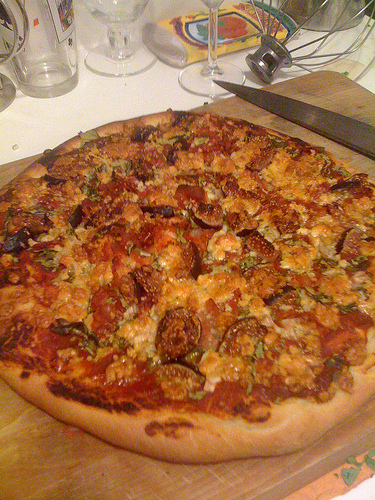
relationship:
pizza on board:
[2, 104, 375, 462] [0, 69, 374, 498]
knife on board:
[213, 75, 374, 159] [0, 69, 374, 498]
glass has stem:
[179, 1, 247, 96] [198, 9, 223, 75]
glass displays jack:
[5, 3, 81, 100] [46, 1, 77, 43]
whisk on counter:
[243, 1, 374, 83] [4, 0, 374, 499]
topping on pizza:
[153, 304, 204, 362] [2, 104, 375, 462]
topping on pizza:
[245, 147, 282, 170] [2, 104, 375, 462]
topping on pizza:
[240, 228, 285, 262] [2, 104, 375, 462]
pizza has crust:
[2, 104, 375, 462] [36, 401, 350, 459]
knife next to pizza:
[213, 75, 374, 159] [2, 104, 375, 462]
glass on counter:
[81, 1, 159, 78] [4, 0, 374, 499]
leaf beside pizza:
[336, 449, 374, 492] [2, 104, 375, 462]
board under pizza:
[0, 69, 374, 498] [2, 104, 375, 462]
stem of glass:
[198, 9, 223, 75] [179, 1, 247, 96]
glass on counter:
[5, 3, 81, 100] [4, 0, 374, 499]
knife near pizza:
[213, 75, 374, 159] [2, 104, 375, 462]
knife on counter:
[213, 75, 374, 159] [4, 0, 374, 499]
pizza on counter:
[2, 104, 375, 462] [4, 0, 374, 499]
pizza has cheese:
[2, 104, 375, 462] [165, 270, 241, 304]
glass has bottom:
[179, 1, 247, 96] [179, 58, 248, 98]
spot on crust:
[146, 418, 198, 441] [36, 401, 350, 459]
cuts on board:
[178, 466, 245, 499] [0, 69, 374, 498]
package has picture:
[143, 1, 303, 69] [215, 14, 250, 40]